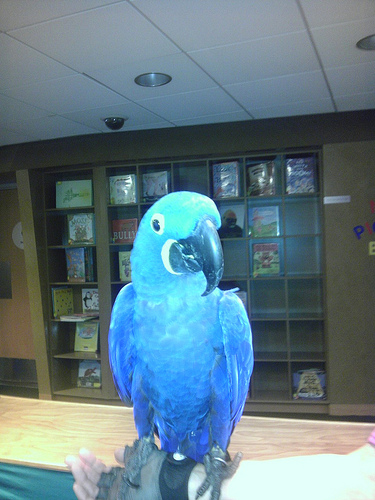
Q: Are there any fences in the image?
A: No, there are no fences.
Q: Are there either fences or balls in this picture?
A: No, there are no fences or balls.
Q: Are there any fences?
A: No, there are no fences.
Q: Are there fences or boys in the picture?
A: No, there are no fences or boys.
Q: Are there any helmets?
A: No, there are no helmets.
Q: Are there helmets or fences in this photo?
A: No, there are no helmets or fences.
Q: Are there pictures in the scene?
A: No, there are no pictures.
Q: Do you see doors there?
A: Yes, there is a door.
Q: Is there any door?
A: Yes, there is a door.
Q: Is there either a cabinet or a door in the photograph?
A: Yes, there is a door.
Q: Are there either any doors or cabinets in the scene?
A: Yes, there is a door.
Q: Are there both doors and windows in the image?
A: No, there is a door but no windows.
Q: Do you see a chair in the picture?
A: No, there are no chairs.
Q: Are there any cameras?
A: Yes, there is a camera.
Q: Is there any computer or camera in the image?
A: Yes, there is a camera.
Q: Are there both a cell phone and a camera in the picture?
A: No, there is a camera but no cell phones.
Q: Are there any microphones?
A: No, there are no microphones.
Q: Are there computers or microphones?
A: No, there are no microphones or computers.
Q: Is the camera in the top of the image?
A: Yes, the camera is in the top of the image.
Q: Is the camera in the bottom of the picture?
A: No, the camera is in the top of the image.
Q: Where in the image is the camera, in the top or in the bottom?
A: The camera is in the top of the image.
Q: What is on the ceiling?
A: The camera is on the ceiling.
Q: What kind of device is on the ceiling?
A: The device is a camera.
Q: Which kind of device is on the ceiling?
A: The device is a camera.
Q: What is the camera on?
A: The camera is on the ceiling.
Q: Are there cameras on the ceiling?
A: Yes, there is a camera on the ceiling.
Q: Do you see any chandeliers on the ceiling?
A: No, there is a camera on the ceiling.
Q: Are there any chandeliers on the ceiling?
A: No, there is a camera on the ceiling.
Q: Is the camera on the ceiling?
A: Yes, the camera is on the ceiling.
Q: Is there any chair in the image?
A: No, there are no chairs.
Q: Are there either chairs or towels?
A: No, there are no chairs or towels.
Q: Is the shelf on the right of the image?
A: Yes, the shelf is on the right of the image.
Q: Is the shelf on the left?
A: No, the shelf is on the right of the image.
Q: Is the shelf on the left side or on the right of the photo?
A: The shelf is on the right of the image.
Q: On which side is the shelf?
A: The shelf is on the right of the image.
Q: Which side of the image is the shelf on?
A: The shelf is on the right of the image.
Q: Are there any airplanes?
A: No, there are no airplanes.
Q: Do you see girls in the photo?
A: No, there are no girls.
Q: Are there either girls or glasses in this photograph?
A: No, there are no girls or glasses.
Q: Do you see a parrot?
A: Yes, there is a parrot.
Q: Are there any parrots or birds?
A: Yes, there is a parrot.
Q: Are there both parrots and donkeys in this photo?
A: No, there is a parrot but no donkeys.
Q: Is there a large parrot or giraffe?
A: Yes, there is a large parrot.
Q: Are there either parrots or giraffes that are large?
A: Yes, the parrot is large.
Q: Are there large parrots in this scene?
A: Yes, there is a large parrot.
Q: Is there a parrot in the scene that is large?
A: Yes, there is a parrot that is large.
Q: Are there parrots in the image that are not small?
A: Yes, there is a large parrot.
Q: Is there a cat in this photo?
A: No, there are no cats.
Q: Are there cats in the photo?
A: No, there are no cats.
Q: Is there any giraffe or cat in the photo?
A: No, there are no cats or giraffes.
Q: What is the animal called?
A: The animal is a parrot.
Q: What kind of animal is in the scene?
A: The animal is a parrot.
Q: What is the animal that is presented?
A: The animal is a parrot.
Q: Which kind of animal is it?
A: The animal is a parrot.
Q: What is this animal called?
A: This is a parrot.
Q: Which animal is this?
A: This is a parrot.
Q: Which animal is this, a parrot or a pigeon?
A: This is a parrot.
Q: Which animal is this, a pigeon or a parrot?
A: This is a parrot.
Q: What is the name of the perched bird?
A: The bird is a parrot.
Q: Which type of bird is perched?
A: The bird is a parrot.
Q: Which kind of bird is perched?
A: The bird is a parrot.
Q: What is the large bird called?
A: The bird is a parrot.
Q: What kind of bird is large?
A: The bird is a parrot.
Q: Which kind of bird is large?
A: The bird is a parrot.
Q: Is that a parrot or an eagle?
A: That is a parrot.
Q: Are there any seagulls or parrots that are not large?
A: No, there is a parrot but it is large.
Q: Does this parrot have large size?
A: Yes, the parrot is large.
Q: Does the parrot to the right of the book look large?
A: Yes, the parrot is large.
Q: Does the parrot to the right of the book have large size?
A: Yes, the parrot is large.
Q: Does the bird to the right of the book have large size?
A: Yes, the parrot is large.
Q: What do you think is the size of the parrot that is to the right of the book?
A: The parrot is large.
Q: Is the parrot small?
A: No, the parrot is large.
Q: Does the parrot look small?
A: No, the parrot is large.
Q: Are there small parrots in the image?
A: No, there is a parrot but it is large.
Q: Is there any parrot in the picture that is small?
A: No, there is a parrot but it is large.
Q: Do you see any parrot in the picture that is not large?
A: No, there is a parrot but it is large.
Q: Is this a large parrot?
A: Yes, this is a large parrot.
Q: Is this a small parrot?
A: No, this is a large parrot.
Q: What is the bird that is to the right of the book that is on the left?
A: The bird is a parrot.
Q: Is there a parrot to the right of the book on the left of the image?
A: Yes, there is a parrot to the right of the book.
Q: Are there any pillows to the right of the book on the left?
A: No, there is a parrot to the right of the book.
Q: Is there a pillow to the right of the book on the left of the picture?
A: No, there is a parrot to the right of the book.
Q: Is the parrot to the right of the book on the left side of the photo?
A: Yes, the parrot is to the right of the book.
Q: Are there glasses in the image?
A: No, there are no glasses.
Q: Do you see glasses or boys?
A: No, there are no glasses or boys.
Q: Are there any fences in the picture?
A: No, there are no fences.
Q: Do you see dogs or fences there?
A: No, there are no fences or dogs.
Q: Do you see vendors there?
A: No, there are no vendors.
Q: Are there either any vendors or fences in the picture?
A: No, there are no vendors or fences.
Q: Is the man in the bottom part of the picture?
A: Yes, the man is in the bottom of the image.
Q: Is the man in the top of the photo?
A: No, the man is in the bottom of the image.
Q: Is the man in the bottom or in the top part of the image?
A: The man is in the bottom of the image.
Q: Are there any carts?
A: No, there are no carts.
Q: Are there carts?
A: No, there are no carts.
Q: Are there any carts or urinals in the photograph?
A: No, there are no carts or urinals.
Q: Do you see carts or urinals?
A: No, there are no carts or urinals.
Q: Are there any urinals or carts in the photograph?
A: No, there are no carts or urinals.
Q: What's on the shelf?
A: The book is on the shelf.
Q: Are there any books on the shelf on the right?
A: Yes, there is a book on the shelf.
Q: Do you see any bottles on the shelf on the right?
A: No, there is a book on the shelf.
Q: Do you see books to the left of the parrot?
A: Yes, there is a book to the left of the parrot.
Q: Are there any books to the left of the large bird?
A: Yes, there is a book to the left of the parrot.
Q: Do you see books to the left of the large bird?
A: Yes, there is a book to the left of the parrot.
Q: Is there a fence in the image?
A: No, there are no fences.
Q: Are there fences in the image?
A: No, there are no fences.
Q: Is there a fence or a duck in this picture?
A: No, there are no fences or ducks.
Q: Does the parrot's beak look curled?
A: Yes, the beak is curled.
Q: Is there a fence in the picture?
A: No, there are no fences.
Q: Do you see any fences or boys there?
A: No, there are no fences or boys.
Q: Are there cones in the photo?
A: No, there are no cones.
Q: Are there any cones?
A: No, there are no cones.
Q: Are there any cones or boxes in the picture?
A: No, there are no cones or boxes.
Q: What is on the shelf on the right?
A: The book is on the shelf.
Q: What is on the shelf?
A: The book is on the shelf.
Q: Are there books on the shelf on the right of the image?
A: Yes, there is a book on the shelf.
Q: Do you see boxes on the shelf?
A: No, there is a book on the shelf.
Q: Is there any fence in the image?
A: No, there are no fences.